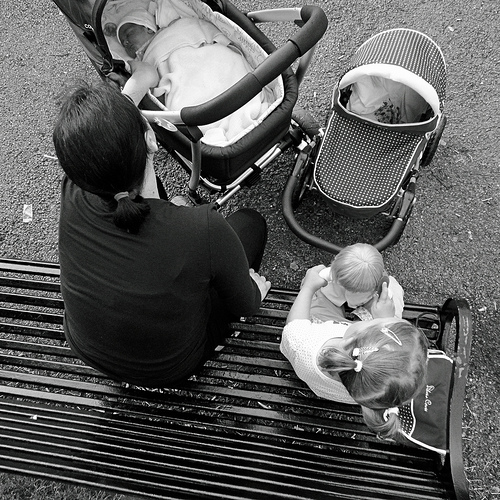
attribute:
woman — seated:
[42, 80, 267, 394]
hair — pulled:
[321, 323, 433, 412]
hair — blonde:
[327, 239, 389, 296]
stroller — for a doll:
[280, 24, 451, 253]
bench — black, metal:
[2, 249, 475, 499]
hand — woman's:
[126, 48, 171, 102]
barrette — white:
[375, 319, 409, 350]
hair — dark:
[54, 78, 149, 231]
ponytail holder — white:
[351, 358, 363, 374]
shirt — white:
[302, 304, 370, 352]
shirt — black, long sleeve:
[47, 180, 278, 432]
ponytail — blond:
[317, 349, 357, 372]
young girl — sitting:
[283, 267, 444, 444]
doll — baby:
[304, 239, 407, 318]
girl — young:
[298, 304, 434, 414]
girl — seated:
[280, 239, 429, 439]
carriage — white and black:
[273, 22, 460, 262]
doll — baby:
[315, 242, 397, 321]